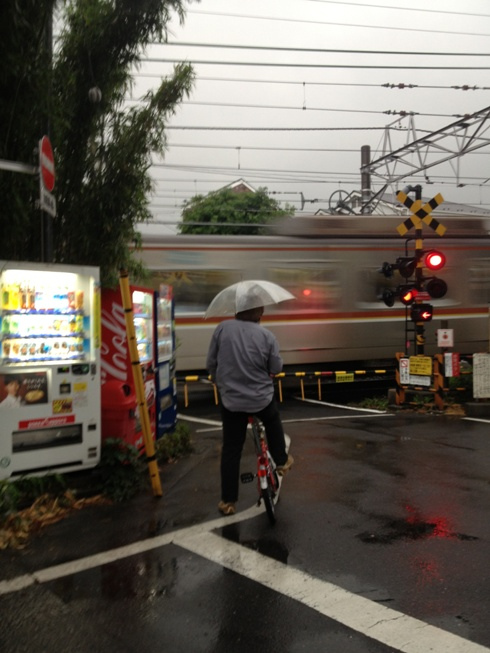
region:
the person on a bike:
[195, 271, 306, 524]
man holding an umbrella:
[193, 271, 299, 413]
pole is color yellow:
[117, 266, 170, 505]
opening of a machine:
[8, 420, 89, 457]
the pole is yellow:
[178, 378, 192, 408]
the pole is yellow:
[276, 375, 287, 402]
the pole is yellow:
[297, 374, 310, 402]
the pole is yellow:
[315, 374, 326, 397]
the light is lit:
[421, 249, 446, 274]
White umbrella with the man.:
[184, 237, 328, 373]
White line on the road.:
[139, 479, 334, 630]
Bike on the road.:
[234, 415, 352, 537]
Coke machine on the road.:
[75, 245, 243, 523]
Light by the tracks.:
[300, 156, 483, 326]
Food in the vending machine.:
[4, 260, 99, 397]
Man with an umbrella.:
[158, 244, 306, 564]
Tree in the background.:
[157, 164, 467, 342]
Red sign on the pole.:
[28, 107, 85, 223]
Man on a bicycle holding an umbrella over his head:
[203, 276, 296, 525]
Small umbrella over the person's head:
[202, 279, 295, 321]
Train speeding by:
[110, 212, 487, 393]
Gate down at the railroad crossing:
[174, 362, 401, 380]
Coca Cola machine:
[99, 286, 159, 458]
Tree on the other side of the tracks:
[176, 179, 294, 230]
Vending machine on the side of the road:
[0, 255, 102, 493]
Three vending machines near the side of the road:
[0, 260, 182, 481]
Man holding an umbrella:
[204, 280, 295, 514]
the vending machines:
[1, 253, 182, 486]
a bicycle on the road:
[245, 408, 294, 526]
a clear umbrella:
[204, 274, 295, 323]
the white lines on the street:
[1, 397, 488, 651]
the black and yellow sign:
[395, 182, 451, 253]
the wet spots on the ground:
[90, 413, 477, 606]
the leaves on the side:
[2, 451, 179, 549]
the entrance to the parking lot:
[172, 361, 398, 411]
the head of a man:
[219, 282, 266, 324]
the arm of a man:
[196, 327, 243, 383]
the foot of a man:
[208, 483, 248, 526]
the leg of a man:
[200, 399, 254, 506]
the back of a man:
[200, 285, 279, 419]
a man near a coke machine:
[67, 243, 333, 469]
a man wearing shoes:
[190, 476, 236, 527]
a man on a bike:
[159, 287, 370, 579]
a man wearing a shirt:
[173, 294, 308, 438]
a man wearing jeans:
[179, 385, 330, 576]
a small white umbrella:
[202, 279, 297, 325]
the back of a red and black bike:
[240, 406, 284, 515]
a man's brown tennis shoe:
[215, 495, 236, 514]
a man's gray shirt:
[203, 318, 282, 418]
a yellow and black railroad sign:
[385, 182, 452, 251]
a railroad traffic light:
[365, 247, 451, 324]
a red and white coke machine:
[93, 276, 158, 458]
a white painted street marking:
[159, 504, 484, 650]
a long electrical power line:
[136, 31, 488, 57]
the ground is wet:
[8, 349, 477, 640]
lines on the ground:
[24, 457, 470, 651]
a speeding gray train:
[129, 213, 481, 376]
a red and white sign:
[27, 129, 67, 201]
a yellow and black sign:
[377, 180, 451, 244]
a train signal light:
[381, 236, 458, 327]